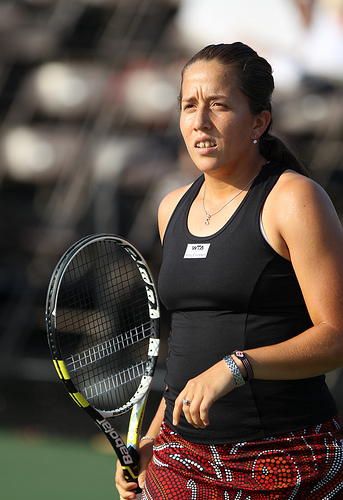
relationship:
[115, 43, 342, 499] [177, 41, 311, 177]
woman has hair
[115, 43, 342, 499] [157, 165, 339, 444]
woman has shirt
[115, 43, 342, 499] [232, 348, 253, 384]
woman has bracelet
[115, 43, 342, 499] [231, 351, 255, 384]
woman has watch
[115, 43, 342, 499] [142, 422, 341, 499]
woman has shorts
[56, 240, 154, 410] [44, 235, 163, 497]
strings on tennis racket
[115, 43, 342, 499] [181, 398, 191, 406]
woman has ring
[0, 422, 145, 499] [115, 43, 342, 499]
tennis court behind woman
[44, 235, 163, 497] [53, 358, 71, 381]
tennis racket has yellow stripes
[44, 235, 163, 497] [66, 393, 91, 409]
tennis racket has yellow stripes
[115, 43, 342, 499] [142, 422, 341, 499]
woman wearing shorts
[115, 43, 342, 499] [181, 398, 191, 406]
woman wearing ring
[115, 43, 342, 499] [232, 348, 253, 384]
woman wearing bracelet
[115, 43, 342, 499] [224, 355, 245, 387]
woman wearing bracelet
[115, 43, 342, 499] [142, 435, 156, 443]
woman wearing bracelet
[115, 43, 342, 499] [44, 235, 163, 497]
woman holding tennis racket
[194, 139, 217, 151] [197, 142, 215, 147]
mouth has teeth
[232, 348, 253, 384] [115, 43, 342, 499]
bracelet on woman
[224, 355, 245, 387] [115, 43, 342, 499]
bracelet on woman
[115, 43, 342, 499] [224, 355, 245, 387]
woman has bracelet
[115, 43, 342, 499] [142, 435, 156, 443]
woman has bracelet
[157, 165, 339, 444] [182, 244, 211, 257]
shirt has label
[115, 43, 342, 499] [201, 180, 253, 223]
woman wearing necklace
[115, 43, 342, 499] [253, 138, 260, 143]
woman wearing earring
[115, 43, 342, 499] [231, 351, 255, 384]
woman wearing watch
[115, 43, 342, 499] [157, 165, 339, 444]
woman wearing shirt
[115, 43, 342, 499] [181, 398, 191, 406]
woman wears ring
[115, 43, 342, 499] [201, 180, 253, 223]
woman has necklace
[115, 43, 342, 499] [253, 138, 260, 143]
woman has earring